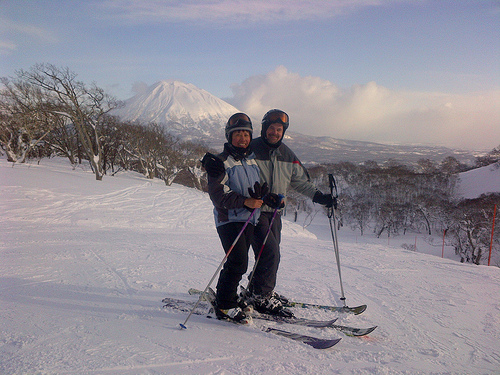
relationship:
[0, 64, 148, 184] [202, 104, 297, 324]
trees behind couple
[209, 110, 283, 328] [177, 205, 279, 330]
woman holding poles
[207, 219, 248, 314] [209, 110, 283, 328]
pants of woman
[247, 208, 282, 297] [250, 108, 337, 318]
pants of man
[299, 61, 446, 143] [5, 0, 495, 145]
cloud in sky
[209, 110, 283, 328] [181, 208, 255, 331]
woman holding ski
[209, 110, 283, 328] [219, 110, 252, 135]
woman wearing helmet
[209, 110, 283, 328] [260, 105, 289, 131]
woman wearing helmet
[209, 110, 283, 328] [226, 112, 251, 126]
woman have goggles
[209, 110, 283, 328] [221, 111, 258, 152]
woman have helmets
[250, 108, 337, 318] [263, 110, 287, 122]
man have goggles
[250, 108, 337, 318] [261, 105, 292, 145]
man have helmets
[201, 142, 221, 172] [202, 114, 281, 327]
arm around woman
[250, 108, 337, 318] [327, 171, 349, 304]
man holding ski pole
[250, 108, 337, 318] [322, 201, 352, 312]
man holding poles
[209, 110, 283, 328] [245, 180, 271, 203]
woman holding glove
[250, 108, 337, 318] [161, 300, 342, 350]
man wearing skis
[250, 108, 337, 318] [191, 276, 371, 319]
man wearing ski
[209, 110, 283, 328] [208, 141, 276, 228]
woman wearing jacket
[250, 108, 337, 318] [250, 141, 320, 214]
man wearing gray jacket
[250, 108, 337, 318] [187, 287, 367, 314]
man holding ski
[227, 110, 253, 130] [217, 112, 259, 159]
goggles on head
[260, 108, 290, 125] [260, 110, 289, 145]
goggles on head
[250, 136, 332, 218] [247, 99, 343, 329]
gray jacket worn by man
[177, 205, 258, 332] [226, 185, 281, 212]
poles in hand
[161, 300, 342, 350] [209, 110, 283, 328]
skis worn by woman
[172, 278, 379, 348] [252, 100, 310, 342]
skis worn by man